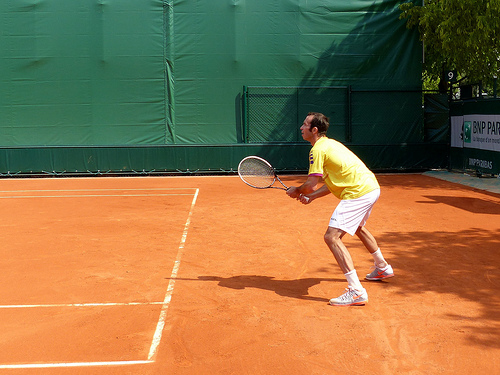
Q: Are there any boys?
A: No, there are no boys.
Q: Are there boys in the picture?
A: No, there are no boys.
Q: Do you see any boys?
A: No, there are no boys.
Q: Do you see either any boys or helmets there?
A: No, there are no boys or helmets.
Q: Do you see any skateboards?
A: No, there are no skateboards.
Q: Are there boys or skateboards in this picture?
A: No, there are no skateboards or boys.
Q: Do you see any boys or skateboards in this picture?
A: No, there are no skateboards or boys.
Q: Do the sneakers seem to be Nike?
A: Yes, the sneakers are nike.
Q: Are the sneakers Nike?
A: Yes, the sneakers are nike.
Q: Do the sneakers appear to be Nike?
A: Yes, the sneakers are nike.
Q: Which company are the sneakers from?
A: The sneakers are from nike.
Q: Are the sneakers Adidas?
A: No, the sneakers are nike.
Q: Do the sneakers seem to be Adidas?
A: No, the sneakers are nike.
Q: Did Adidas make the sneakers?
A: No, the sneakers were made by nike.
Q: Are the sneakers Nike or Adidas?
A: The sneakers are nike.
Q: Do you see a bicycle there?
A: No, there are no bicycles.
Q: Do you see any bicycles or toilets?
A: No, there are no bicycles or toilets.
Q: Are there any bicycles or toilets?
A: No, there are no bicycles or toilets.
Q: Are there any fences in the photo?
A: Yes, there is a fence.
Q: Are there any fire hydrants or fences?
A: Yes, there is a fence.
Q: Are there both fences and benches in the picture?
A: No, there is a fence but no benches.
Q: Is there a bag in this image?
A: No, there are no bags.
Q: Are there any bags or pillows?
A: No, there are no bags or pillows.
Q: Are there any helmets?
A: No, there are no helmets.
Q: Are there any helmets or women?
A: No, there are no helmets or women.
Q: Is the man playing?
A: Yes, the man is playing.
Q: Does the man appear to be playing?
A: Yes, the man is playing.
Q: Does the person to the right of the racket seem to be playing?
A: Yes, the man is playing.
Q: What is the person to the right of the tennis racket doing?
A: The man is playing.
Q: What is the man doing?
A: The man is playing.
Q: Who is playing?
A: The man is playing.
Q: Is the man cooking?
A: No, the man is playing.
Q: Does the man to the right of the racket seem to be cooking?
A: No, the man is playing.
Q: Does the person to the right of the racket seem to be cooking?
A: No, the man is playing.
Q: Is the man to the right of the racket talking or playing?
A: The man is playing.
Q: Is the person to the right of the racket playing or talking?
A: The man is playing.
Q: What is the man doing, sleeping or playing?
A: The man is playing.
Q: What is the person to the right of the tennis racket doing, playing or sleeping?
A: The man is playing.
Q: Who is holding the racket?
A: The man is holding the racket.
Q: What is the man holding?
A: The man is holding the racket.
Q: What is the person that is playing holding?
A: The man is holding the racket.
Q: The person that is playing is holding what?
A: The man is holding the racket.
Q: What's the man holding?
A: The man is holding the racket.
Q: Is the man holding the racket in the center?
A: Yes, the man is holding the tennis racket.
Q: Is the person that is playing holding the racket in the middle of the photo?
A: Yes, the man is holding the tennis racket.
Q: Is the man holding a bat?
A: No, the man is holding the tennis racket.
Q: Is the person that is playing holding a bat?
A: No, the man is holding the tennis racket.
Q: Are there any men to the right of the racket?
A: Yes, there is a man to the right of the racket.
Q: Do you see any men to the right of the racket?
A: Yes, there is a man to the right of the racket.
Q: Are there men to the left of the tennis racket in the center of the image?
A: No, the man is to the right of the racket.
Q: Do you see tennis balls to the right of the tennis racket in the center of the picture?
A: No, there is a man to the right of the tennis racket.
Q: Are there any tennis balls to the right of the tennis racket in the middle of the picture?
A: No, there is a man to the right of the tennis racket.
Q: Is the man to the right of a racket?
A: Yes, the man is to the right of a racket.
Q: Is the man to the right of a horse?
A: No, the man is to the right of a racket.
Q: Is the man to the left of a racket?
A: No, the man is to the right of a racket.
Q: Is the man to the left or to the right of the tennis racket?
A: The man is to the right of the tennis racket.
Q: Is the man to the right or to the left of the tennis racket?
A: The man is to the right of the tennis racket.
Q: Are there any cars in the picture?
A: No, there are no cars.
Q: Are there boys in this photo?
A: No, there are no boys.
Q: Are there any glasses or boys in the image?
A: No, there are no boys or glasses.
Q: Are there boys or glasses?
A: No, there are no boys or glasses.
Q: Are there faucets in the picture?
A: No, there are no faucets.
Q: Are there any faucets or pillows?
A: No, there are no faucets or pillows.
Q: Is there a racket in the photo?
A: Yes, there is a racket.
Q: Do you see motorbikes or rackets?
A: Yes, there is a racket.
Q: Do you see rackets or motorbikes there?
A: Yes, there is a racket.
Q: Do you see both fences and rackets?
A: Yes, there are both a racket and a fence.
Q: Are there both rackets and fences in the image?
A: Yes, there are both a racket and a fence.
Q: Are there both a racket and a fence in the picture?
A: Yes, there are both a racket and a fence.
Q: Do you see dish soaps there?
A: No, there are no dish soaps.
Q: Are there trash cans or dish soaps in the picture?
A: No, there are no dish soaps or trash cans.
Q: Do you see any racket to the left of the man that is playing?
A: Yes, there is a racket to the left of the man.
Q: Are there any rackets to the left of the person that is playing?
A: Yes, there is a racket to the left of the man.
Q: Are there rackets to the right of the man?
A: No, the racket is to the left of the man.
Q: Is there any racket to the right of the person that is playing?
A: No, the racket is to the left of the man.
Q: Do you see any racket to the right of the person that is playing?
A: No, the racket is to the left of the man.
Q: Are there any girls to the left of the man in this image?
A: No, there is a racket to the left of the man.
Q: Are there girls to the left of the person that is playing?
A: No, there is a racket to the left of the man.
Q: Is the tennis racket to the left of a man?
A: Yes, the tennis racket is to the left of a man.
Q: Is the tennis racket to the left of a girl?
A: No, the tennis racket is to the left of a man.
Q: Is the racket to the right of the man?
A: No, the racket is to the left of the man.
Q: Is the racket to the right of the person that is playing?
A: No, the racket is to the left of the man.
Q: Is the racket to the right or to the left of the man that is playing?
A: The racket is to the left of the man.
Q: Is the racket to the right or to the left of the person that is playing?
A: The racket is to the left of the man.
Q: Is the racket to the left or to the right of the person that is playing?
A: The racket is to the left of the man.